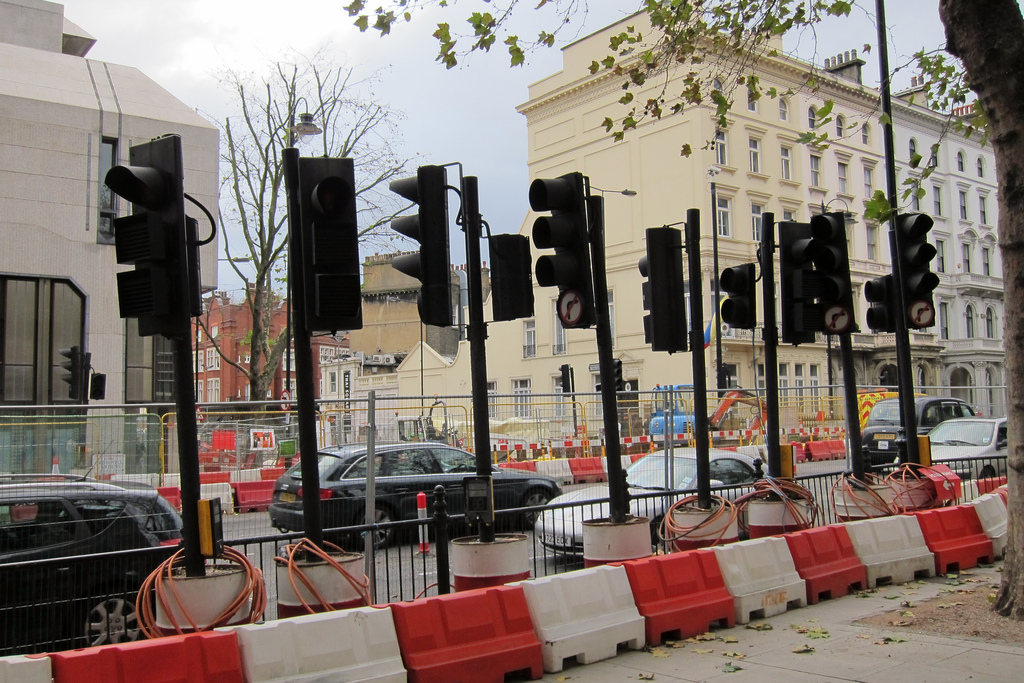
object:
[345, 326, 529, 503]
wall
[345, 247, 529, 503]
building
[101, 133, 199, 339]
streetlight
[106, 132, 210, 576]
pole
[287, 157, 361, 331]
streetlight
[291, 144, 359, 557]
pole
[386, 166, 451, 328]
streetlight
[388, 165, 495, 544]
pole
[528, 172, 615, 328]
streetlight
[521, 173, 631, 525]
pole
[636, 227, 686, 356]
streetlight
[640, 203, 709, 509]
pole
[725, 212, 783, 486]
pole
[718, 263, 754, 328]
streetlight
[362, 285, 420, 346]
wall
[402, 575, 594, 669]
wall building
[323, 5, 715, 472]
wall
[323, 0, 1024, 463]
building